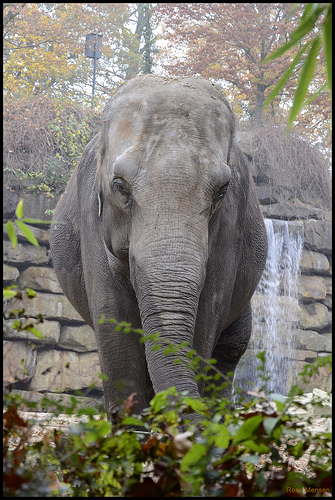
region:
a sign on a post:
[83, 27, 103, 107]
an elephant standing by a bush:
[46, 71, 269, 421]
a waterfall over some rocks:
[248, 214, 298, 401]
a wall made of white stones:
[3, 155, 333, 423]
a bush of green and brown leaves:
[2, 315, 333, 497]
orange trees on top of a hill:
[0, 2, 332, 150]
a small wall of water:
[248, 216, 298, 408]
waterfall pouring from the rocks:
[223, 215, 319, 410]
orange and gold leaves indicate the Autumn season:
[0, 3, 334, 164]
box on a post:
[82, 27, 106, 113]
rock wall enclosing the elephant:
[1, 140, 332, 407]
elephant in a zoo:
[57, 72, 270, 439]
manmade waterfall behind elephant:
[225, 207, 317, 423]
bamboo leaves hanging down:
[261, 0, 333, 129]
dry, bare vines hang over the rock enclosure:
[259, 128, 326, 221]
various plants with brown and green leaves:
[4, 392, 334, 496]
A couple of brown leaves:
[135, 480, 177, 495]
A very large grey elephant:
[50, 74, 269, 433]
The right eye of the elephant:
[112, 176, 130, 199]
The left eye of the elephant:
[205, 174, 225, 204]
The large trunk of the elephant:
[134, 201, 201, 420]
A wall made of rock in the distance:
[8, 251, 39, 387]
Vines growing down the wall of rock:
[12, 118, 65, 168]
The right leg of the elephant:
[93, 287, 135, 418]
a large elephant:
[44, 50, 278, 450]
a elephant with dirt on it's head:
[131, 59, 219, 110]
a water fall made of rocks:
[238, 207, 314, 368]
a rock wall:
[0, 212, 50, 398]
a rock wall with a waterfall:
[244, 201, 325, 392]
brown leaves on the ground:
[13, 399, 306, 499]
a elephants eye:
[108, 168, 137, 210]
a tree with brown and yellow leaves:
[202, 14, 290, 104]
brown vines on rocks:
[260, 136, 319, 187]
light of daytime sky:
[3, 3, 333, 131]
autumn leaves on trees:
[3, 3, 331, 120]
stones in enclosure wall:
[3, 136, 330, 411]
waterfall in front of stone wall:
[239, 219, 305, 404]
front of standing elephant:
[49, 75, 267, 427]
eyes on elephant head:
[114, 177, 228, 196]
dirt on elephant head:
[125, 75, 227, 104]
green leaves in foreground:
[3, 316, 328, 493]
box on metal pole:
[84, 33, 102, 107]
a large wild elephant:
[46, 71, 269, 454]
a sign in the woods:
[71, 22, 109, 110]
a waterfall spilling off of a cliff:
[229, 194, 306, 424]